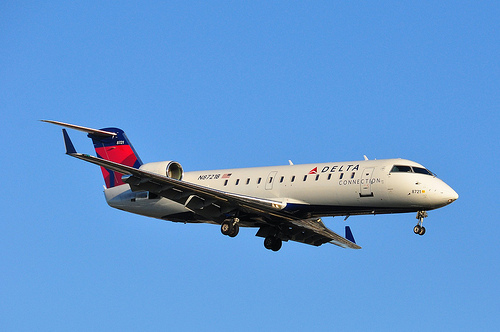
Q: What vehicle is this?
A: Airplane.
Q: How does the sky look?
A: Cloudless.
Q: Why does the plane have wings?
A: To be able to fly.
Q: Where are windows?
A: On side of a plane.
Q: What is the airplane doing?
A: Flying.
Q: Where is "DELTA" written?
A: On side of plane.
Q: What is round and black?
A: The wheels.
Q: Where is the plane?
A: In the sky.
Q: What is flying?
A: An airplane.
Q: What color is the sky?
A: Blue.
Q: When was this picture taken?
A: During the day.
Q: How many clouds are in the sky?
A: Zero.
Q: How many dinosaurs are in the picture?
A: Zero.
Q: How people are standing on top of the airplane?
A: Zero.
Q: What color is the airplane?
A: White.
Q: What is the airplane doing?
A: Flying.